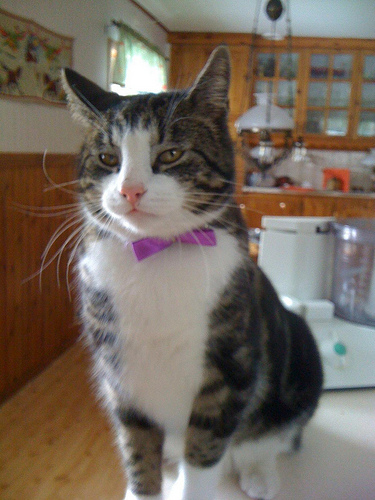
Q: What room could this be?
A: It is a kitchen.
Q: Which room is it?
A: It is a kitchen.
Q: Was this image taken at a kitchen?
A: Yes, it was taken in a kitchen.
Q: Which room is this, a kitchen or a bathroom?
A: It is a kitchen.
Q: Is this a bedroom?
A: No, it is a kitchen.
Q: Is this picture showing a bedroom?
A: No, the picture is showing a kitchen.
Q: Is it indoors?
A: Yes, it is indoors.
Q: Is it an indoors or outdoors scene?
A: It is indoors.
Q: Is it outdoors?
A: No, it is indoors.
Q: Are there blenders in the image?
A: Yes, there is a blender.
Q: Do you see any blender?
A: Yes, there is a blender.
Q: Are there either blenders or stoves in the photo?
A: Yes, there is a blender.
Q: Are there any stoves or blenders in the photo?
A: Yes, there is a blender.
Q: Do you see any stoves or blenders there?
A: Yes, there is a blender.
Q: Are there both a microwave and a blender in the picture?
A: No, there is a blender but no microwaves.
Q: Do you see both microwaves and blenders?
A: No, there is a blender but no microwaves.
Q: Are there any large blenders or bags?
A: Yes, there is a large blender.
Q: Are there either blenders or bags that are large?
A: Yes, the blender is large.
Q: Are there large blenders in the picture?
A: Yes, there is a large blender.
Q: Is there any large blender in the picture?
A: Yes, there is a large blender.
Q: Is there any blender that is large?
A: Yes, there is a blender that is large.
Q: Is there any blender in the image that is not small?
A: Yes, there is a large blender.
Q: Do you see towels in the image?
A: No, there are no towels.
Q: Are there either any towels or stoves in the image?
A: No, there are no towels or stoves.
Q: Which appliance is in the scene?
A: The appliance is a blender.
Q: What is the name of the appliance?
A: The appliance is a blender.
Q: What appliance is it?
A: The appliance is a blender.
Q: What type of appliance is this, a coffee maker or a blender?
A: This is a blender.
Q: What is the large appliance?
A: The appliance is a blender.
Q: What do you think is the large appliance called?
A: The appliance is a blender.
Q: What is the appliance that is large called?
A: The appliance is a blender.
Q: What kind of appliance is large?
A: The appliance is a blender.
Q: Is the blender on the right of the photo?
A: Yes, the blender is on the right of the image.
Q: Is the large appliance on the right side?
A: Yes, the blender is on the right of the image.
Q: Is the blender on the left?
A: No, the blender is on the right of the image.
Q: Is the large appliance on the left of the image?
A: No, the blender is on the right of the image.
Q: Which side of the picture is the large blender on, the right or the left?
A: The blender is on the right of the image.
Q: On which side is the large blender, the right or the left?
A: The blender is on the right of the image.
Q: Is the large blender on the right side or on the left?
A: The blender is on the right of the image.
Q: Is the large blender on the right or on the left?
A: The blender is on the right of the image.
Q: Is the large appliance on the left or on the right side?
A: The blender is on the right of the image.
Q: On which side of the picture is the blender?
A: The blender is on the right of the image.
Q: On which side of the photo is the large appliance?
A: The blender is on the right of the image.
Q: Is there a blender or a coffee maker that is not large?
A: No, there is a blender but it is large.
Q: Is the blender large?
A: Yes, the blender is large.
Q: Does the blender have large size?
A: Yes, the blender is large.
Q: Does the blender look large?
A: Yes, the blender is large.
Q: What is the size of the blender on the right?
A: The blender is large.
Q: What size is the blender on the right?
A: The blender is large.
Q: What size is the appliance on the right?
A: The blender is large.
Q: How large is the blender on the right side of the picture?
A: The blender is large.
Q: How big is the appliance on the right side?
A: The blender is large.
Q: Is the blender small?
A: No, the blender is large.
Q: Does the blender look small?
A: No, the blender is large.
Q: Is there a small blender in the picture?
A: No, there is a blender but it is large.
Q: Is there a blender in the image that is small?
A: No, there is a blender but it is large.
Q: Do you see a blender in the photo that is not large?
A: No, there is a blender but it is large.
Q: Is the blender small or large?
A: The blender is large.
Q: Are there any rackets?
A: No, there are no rackets.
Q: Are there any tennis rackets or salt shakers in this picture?
A: No, there are no tennis rackets or salt shakers.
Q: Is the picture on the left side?
A: Yes, the picture is on the left of the image.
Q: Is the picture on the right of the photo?
A: No, the picture is on the left of the image.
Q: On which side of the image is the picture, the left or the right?
A: The picture is on the left of the image.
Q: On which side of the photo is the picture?
A: The picture is on the left of the image.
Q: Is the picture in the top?
A: Yes, the picture is in the top of the image.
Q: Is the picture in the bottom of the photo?
A: No, the picture is in the top of the image.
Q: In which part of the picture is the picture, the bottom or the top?
A: The picture is in the top of the image.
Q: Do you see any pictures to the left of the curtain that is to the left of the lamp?
A: Yes, there is a picture to the left of the curtain.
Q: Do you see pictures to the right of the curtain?
A: No, the picture is to the left of the curtain.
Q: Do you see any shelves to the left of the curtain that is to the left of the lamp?
A: No, there is a picture to the left of the curtain.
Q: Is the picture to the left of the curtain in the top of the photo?
A: Yes, the picture is to the left of the curtain.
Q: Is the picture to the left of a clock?
A: No, the picture is to the left of the curtain.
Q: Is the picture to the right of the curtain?
A: No, the picture is to the left of the curtain.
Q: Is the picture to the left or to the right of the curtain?
A: The picture is to the left of the curtain.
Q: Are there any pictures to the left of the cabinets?
A: Yes, there is a picture to the left of the cabinets.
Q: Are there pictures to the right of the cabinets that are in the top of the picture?
A: No, the picture is to the left of the cabinets.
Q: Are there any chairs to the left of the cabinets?
A: No, there is a picture to the left of the cabinets.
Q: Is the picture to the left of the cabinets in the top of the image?
A: Yes, the picture is to the left of the cabinets.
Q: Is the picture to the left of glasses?
A: No, the picture is to the left of the cabinets.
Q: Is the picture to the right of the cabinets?
A: No, the picture is to the left of the cabinets.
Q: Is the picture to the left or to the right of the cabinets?
A: The picture is to the left of the cabinets.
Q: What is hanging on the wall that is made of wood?
A: The picture is hanging on the wall.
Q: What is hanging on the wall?
A: The picture is hanging on the wall.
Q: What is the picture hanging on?
A: The picture is hanging on the wall.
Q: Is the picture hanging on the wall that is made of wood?
A: Yes, the picture is hanging on the wall.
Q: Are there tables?
A: Yes, there is a table.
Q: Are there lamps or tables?
A: Yes, there is a table.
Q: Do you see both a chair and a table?
A: No, there is a table but no chairs.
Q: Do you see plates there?
A: No, there are no plates.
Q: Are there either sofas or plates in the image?
A: No, there are no plates or sofas.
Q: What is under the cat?
A: The table is under the cat.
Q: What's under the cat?
A: The table is under the cat.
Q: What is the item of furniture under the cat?
A: The piece of furniture is a table.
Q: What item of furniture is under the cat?
A: The piece of furniture is a table.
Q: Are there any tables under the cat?
A: Yes, there is a table under the cat.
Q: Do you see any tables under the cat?
A: Yes, there is a table under the cat.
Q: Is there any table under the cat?
A: Yes, there is a table under the cat.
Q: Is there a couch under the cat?
A: No, there is a table under the cat.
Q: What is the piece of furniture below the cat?
A: The piece of furniture is a table.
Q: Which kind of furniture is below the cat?
A: The piece of furniture is a table.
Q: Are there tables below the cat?
A: Yes, there is a table below the cat.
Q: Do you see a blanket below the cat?
A: No, there is a table below the cat.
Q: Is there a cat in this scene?
A: Yes, there is a cat.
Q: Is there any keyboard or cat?
A: Yes, there is a cat.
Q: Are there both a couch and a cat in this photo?
A: No, there is a cat but no couches.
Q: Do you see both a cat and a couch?
A: No, there is a cat but no couches.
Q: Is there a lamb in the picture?
A: No, there are no lambs.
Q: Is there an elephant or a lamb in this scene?
A: No, there are no lambs or elephants.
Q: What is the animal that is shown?
A: The animal is a cat.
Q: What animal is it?
A: The animal is a cat.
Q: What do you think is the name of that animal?
A: This is a cat.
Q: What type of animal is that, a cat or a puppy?
A: This is a cat.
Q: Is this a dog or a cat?
A: This is a cat.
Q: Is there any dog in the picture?
A: No, there are no dogs.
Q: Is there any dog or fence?
A: No, there are no dogs or fences.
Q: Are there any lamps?
A: Yes, there is a lamp.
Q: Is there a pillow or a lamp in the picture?
A: Yes, there is a lamp.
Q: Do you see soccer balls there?
A: No, there are no soccer balls.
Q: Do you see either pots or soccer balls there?
A: No, there are no soccer balls or pots.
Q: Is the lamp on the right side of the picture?
A: Yes, the lamp is on the right of the image.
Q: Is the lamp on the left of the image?
A: No, the lamp is on the right of the image.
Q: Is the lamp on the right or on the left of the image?
A: The lamp is on the right of the image.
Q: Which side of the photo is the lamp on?
A: The lamp is on the right of the image.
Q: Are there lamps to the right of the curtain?
A: Yes, there is a lamp to the right of the curtain.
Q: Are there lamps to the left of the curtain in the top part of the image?
A: No, the lamp is to the right of the curtain.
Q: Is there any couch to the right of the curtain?
A: No, there is a lamp to the right of the curtain.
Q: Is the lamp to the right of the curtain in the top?
A: Yes, the lamp is to the right of the curtain.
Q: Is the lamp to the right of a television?
A: No, the lamp is to the right of the curtain.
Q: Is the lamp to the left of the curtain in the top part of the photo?
A: No, the lamp is to the right of the curtain.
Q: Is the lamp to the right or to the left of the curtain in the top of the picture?
A: The lamp is to the right of the curtain.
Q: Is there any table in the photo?
A: Yes, there is a table.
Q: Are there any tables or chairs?
A: Yes, there is a table.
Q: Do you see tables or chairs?
A: Yes, there is a table.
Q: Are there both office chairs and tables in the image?
A: No, there is a table but no office chairs.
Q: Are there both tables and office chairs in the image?
A: No, there is a table but no office chairs.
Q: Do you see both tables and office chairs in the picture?
A: No, there is a table but no office chairs.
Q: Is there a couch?
A: No, there are no couches.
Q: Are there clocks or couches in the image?
A: No, there are no couches or clocks.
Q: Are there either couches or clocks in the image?
A: No, there are no couches or clocks.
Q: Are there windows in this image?
A: Yes, there is a window.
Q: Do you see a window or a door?
A: Yes, there is a window.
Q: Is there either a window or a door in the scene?
A: Yes, there is a window.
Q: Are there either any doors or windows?
A: Yes, there is a window.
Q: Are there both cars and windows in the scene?
A: No, there is a window but no cars.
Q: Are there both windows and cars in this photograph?
A: No, there is a window but no cars.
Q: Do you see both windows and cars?
A: No, there is a window but no cars.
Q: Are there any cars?
A: No, there are no cars.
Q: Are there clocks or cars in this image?
A: No, there are no cars or clocks.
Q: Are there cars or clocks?
A: No, there are no cars or clocks.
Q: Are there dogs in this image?
A: No, there are no dogs.